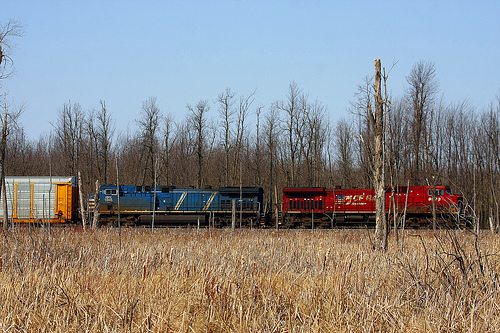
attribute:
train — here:
[0, 175, 470, 232]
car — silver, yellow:
[0, 175, 80, 226]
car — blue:
[89, 183, 264, 224]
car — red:
[280, 185, 465, 229]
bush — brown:
[405, 192, 499, 325]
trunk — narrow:
[369, 59, 388, 251]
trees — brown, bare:
[1, 85, 498, 236]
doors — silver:
[3, 180, 56, 220]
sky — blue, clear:
[0, 0, 499, 151]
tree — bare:
[405, 58, 436, 188]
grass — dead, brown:
[1, 225, 498, 331]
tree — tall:
[368, 57, 388, 251]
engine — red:
[280, 187, 467, 227]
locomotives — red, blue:
[1, 175, 467, 230]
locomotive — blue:
[89, 182, 268, 229]